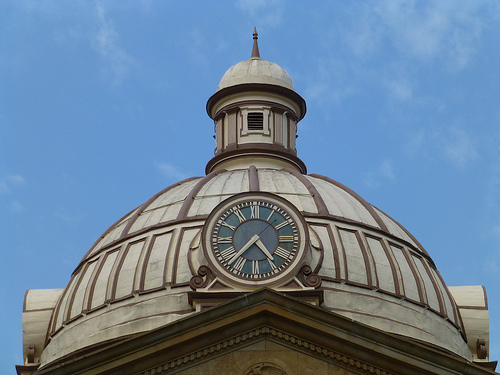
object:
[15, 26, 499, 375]
tower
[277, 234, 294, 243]
numeral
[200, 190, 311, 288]
clock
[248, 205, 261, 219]
numeral 12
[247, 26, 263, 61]
top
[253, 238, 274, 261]
hour hand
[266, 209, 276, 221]
numeral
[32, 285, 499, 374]
facade